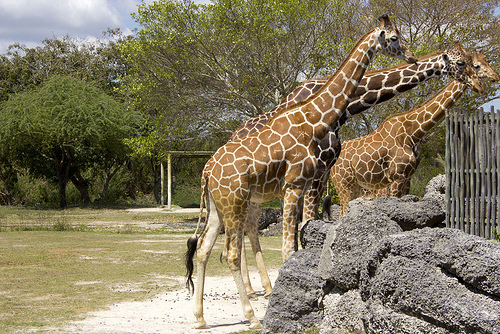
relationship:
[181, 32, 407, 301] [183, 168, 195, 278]
giraffe has tail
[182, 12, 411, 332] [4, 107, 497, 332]
giraffe are in zoo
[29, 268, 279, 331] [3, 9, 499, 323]
dirt inside enclosure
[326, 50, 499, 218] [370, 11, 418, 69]
giraffe has head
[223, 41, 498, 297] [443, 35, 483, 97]
giraffe has head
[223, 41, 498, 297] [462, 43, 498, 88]
giraffe has head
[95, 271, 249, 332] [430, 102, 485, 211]
ground by fence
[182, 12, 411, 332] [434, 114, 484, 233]
giraffe looking over fence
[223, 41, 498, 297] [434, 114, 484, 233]
giraffe looking over fence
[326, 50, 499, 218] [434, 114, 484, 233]
giraffe looking over fence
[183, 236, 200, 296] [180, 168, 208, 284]
black hair coming from tail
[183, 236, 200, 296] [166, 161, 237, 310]
black hair coming from tail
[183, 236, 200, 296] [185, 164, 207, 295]
black hair coming from tail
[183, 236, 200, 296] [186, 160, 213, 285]
black hair coming from tail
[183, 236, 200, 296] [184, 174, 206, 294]
black hair coming from tail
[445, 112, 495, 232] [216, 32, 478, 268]
fence by giraffes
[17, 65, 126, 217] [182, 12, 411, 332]
tree by giraffe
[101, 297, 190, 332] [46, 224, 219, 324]
sand on ground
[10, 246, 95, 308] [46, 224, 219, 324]
grass on ground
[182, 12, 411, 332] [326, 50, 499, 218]
giraffe with giraffe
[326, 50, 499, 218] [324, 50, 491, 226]
giraffe with giraffes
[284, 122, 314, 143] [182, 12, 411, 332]
spots on a giraffe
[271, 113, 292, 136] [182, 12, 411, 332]
spots on a giraffe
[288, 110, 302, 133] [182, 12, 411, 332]
spots on a giraffe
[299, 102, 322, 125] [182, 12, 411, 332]
spots on a giraffe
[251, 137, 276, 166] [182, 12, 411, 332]
spots on a giraffe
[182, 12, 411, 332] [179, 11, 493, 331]
giraffe in a herd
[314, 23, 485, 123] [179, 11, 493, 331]
giraffe in a herd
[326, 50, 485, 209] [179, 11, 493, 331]
giraffe in a herd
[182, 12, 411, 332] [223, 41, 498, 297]
giraffe together with giraffe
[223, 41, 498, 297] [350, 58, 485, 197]
giraffe together with giraffe